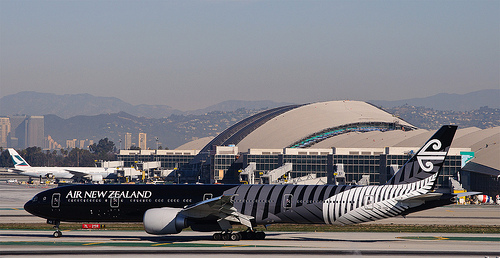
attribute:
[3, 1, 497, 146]
sky — blue 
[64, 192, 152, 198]
letters — white 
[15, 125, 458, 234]
plane — side 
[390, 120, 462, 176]
tail — white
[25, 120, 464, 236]
airplane — black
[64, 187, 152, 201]
logo — Air New Zealand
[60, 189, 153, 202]
logo — Air New Zealand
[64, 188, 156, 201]
logo — Air New Zealand